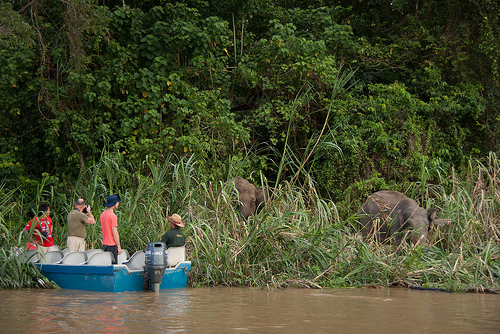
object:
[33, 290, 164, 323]
reflection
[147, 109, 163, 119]
leaves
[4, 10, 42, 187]
tree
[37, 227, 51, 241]
camera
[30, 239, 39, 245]
hands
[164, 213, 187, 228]
hat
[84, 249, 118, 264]
seats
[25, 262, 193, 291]
boat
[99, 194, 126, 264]
man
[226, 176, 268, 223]
elephants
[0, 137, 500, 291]
grass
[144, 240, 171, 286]
motor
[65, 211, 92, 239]
shirt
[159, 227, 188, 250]
shirt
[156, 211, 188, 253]
man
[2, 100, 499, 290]
bushes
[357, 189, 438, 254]
elephant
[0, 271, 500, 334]
river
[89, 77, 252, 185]
trees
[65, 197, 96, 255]
man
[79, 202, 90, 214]
camera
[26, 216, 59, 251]
shirt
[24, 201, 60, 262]
people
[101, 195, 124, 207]
hat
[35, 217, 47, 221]
neck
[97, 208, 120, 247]
shirt